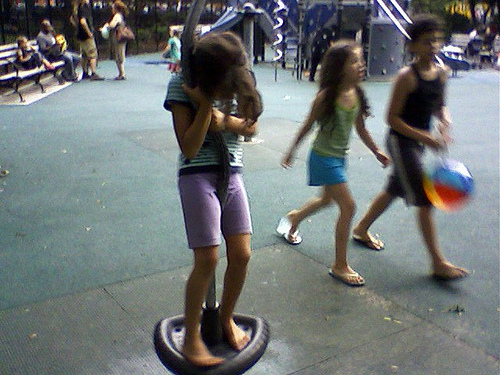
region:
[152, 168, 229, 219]
Girl wearing purple shorts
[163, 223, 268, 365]
girl on a pogo stick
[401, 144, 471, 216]
boy holding a ball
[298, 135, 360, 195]
girl wearing blue shorts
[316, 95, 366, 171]
girl wearing green shirt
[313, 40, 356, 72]
girl with brown hair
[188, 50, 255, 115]
girl with her head down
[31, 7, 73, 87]
people seating on a bench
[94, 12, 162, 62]
woman with a pocketbood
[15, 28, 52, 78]
girl on a bench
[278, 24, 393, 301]
a small girl wearing flip flops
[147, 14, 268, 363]
a small girl barefoot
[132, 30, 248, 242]
a small girl wearing a striped shirt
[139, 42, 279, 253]
a small girl wearing purple shorts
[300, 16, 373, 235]
a small girl wearing blue shorts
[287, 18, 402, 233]
a small girl wearing a tank top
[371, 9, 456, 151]
a small boy wearing a black tank top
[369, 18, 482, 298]
a small boy wearing flip flops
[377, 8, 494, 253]
a small boy wearing shorts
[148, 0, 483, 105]
a playground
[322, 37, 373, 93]
the head of a girl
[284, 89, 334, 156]
the arm of a girl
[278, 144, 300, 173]
the hand of a girl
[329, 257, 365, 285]
the foot of a girl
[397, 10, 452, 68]
the head of a boy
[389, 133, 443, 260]
the leg of a boy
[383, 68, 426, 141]
the arm of a boy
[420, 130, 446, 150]
the hand of a boy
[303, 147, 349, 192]
a pair of blue shorts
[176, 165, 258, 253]
a pair of purple shorts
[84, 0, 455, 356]
kids playing in the park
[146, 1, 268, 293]
girl holding a pole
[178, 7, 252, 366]
the pole is black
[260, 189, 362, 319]
girl is wearing flip flops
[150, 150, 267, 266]
girl is wearing shorts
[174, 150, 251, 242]
the shorts are purple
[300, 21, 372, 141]
the girl has curly hair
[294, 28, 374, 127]
the hair is brown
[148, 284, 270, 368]
the feet are bare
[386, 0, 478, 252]
the kid is holding a ball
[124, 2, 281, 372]
a girl on a swing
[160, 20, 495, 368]
three kids at a park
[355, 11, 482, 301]
a boy walking at a park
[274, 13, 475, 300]
two kids walking at a park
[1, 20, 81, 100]
a man and child sitting on a bench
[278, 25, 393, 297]
a girl walking at the park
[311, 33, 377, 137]
a girl with long hair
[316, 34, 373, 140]
a girl with brown hair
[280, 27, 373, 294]
a girl wearing flip flops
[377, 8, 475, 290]
a boy holding a ball